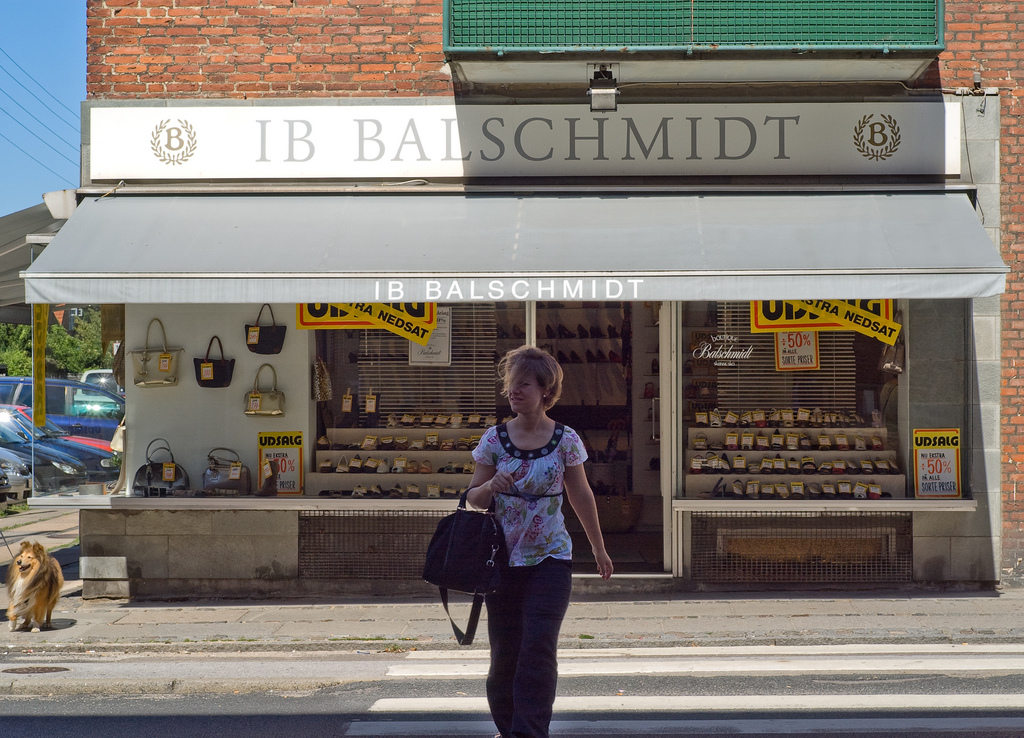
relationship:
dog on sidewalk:
[1, 541, 88, 643] [1, 524, 1004, 734]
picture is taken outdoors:
[26, 11, 994, 725] [13, 33, 994, 708]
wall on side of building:
[302, 298, 540, 510] [10, 8, 1022, 607]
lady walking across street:
[470, 346, 613, 731] [3, 459, 1017, 732]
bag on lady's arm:
[418, 484, 507, 645] [463, 424, 513, 507]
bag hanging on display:
[234, 368, 314, 435] [26, 269, 981, 503]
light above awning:
[571, 67, 645, 130] [447, 33, 960, 126]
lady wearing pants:
[447, 327, 628, 738] [456, 564, 584, 733]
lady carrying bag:
[447, 327, 628, 738] [405, 482, 524, 621]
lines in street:
[681, 676, 770, 729] [22, 592, 978, 705]